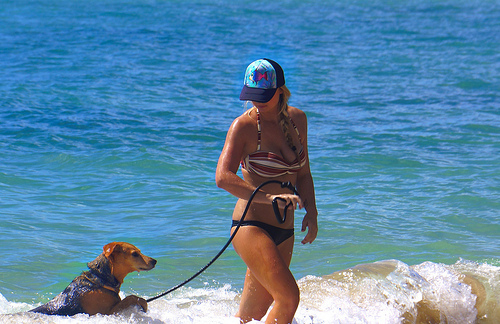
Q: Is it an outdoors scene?
A: Yes, it is outdoors.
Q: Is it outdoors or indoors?
A: It is outdoors.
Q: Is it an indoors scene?
A: No, it is outdoors.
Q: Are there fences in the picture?
A: No, there are no fences.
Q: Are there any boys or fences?
A: No, there are no fences or boys.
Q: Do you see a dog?
A: Yes, there is a dog.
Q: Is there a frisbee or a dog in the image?
A: Yes, there is a dog.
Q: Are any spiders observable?
A: No, there are no spiders.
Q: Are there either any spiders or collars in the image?
A: No, there are no spiders or collars.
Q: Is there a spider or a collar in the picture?
A: No, there are no spiders or collars.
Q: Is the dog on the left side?
A: Yes, the dog is on the left of the image.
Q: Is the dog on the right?
A: No, the dog is on the left of the image.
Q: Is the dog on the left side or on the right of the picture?
A: The dog is on the left of the image.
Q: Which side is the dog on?
A: The dog is on the left of the image.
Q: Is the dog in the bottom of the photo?
A: Yes, the dog is in the bottom of the image.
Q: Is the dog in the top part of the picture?
A: No, the dog is in the bottom of the image.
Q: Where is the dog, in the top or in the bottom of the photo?
A: The dog is in the bottom of the image.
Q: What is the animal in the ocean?
A: The animal is a dog.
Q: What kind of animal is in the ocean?
A: The animal is a dog.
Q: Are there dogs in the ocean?
A: Yes, there is a dog in the ocean.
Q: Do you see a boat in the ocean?
A: No, there is a dog in the ocean.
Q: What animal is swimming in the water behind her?
A: The dog is swimming in the water.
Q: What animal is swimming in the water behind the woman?
A: The animal is a dog.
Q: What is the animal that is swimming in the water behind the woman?
A: The animal is a dog.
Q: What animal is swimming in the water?
A: The animal is a dog.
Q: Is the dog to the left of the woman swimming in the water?
A: Yes, the dog is swimming in the water.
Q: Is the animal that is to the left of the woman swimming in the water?
A: Yes, the dog is swimming in the water.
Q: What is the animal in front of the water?
A: The animal is a dog.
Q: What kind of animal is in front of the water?
A: The animal is a dog.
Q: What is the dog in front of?
A: The dog is in front of the water.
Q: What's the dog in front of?
A: The dog is in front of the water.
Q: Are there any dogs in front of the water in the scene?
A: Yes, there is a dog in front of the water.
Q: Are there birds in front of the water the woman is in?
A: No, there is a dog in front of the water.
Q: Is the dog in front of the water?
A: Yes, the dog is in front of the water.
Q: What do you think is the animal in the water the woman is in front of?
A: The animal is a dog.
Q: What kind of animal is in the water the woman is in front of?
A: The animal is a dog.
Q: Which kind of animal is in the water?
A: The animal is a dog.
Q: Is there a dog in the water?
A: Yes, there is a dog in the water.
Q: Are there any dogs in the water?
A: Yes, there is a dog in the water.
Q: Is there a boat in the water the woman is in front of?
A: No, there is a dog in the water.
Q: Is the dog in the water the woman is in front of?
A: Yes, the dog is in the water.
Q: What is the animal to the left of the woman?
A: The animal is a dog.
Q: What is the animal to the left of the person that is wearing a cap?
A: The animal is a dog.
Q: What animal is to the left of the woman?
A: The animal is a dog.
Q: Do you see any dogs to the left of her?
A: Yes, there is a dog to the left of the woman.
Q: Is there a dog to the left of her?
A: Yes, there is a dog to the left of the woman.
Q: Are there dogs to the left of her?
A: Yes, there is a dog to the left of the woman.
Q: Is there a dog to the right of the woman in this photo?
A: No, the dog is to the left of the woman.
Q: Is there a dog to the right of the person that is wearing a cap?
A: No, the dog is to the left of the woman.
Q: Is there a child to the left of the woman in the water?
A: No, there is a dog to the left of the woman.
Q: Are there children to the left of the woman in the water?
A: No, there is a dog to the left of the woman.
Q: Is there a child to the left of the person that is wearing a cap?
A: No, there is a dog to the left of the woman.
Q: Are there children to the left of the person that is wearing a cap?
A: No, there is a dog to the left of the woman.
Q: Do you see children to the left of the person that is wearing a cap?
A: No, there is a dog to the left of the woman.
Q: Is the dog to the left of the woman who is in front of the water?
A: Yes, the dog is to the left of the woman.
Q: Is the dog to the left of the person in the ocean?
A: Yes, the dog is to the left of the woman.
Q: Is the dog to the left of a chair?
A: No, the dog is to the left of the woman.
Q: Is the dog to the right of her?
A: No, the dog is to the left of a woman.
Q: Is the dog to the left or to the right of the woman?
A: The dog is to the left of the woman.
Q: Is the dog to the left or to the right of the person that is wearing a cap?
A: The dog is to the left of the woman.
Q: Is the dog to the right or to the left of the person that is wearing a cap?
A: The dog is to the left of the woman.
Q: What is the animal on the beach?
A: The animal is a dog.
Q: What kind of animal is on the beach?
A: The animal is a dog.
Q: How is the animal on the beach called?
A: The animal is a dog.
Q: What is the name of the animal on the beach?
A: The animal is a dog.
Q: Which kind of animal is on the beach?
A: The animal is a dog.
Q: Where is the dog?
A: The dog is on the beach.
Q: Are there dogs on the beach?
A: Yes, there is a dog on the beach.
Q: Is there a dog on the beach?
A: Yes, there is a dog on the beach.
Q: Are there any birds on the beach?
A: No, there is a dog on the beach.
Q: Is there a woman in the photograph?
A: Yes, there is a woman.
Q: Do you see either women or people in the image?
A: Yes, there is a woman.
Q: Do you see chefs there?
A: No, there are no chefs.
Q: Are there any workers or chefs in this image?
A: No, there are no chefs or workers.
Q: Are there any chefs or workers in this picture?
A: No, there are no chefs or workers.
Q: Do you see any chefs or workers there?
A: No, there are no chefs or workers.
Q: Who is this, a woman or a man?
A: This is a woman.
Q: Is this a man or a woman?
A: This is a woman.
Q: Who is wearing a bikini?
A: The woman is wearing a bikini.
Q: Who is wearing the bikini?
A: The woman is wearing a bikini.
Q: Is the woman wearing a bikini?
A: Yes, the woman is wearing a bikini.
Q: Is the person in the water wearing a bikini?
A: Yes, the woman is wearing a bikini.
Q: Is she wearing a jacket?
A: No, the woman is wearing a bikini.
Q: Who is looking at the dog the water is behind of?
A: The woman is looking at the dog.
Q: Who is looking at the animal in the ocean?
A: The woman is looking at the dog.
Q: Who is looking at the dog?
A: The woman is looking at the dog.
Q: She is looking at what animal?
A: The woman is looking at the dog.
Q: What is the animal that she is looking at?
A: The animal is a dog.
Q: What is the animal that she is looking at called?
A: The animal is a dog.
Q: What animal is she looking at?
A: The woman is looking at the dog.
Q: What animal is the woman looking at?
A: The woman is looking at the dog.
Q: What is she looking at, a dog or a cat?
A: The woman is looking at a dog.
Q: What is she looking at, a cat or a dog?
A: The woman is looking at a dog.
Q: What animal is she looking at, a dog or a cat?
A: The woman is looking at a dog.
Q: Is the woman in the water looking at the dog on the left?
A: Yes, the woman is looking at the dog.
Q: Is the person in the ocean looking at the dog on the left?
A: Yes, the woman is looking at the dog.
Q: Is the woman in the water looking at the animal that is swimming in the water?
A: Yes, the woman is looking at the dog.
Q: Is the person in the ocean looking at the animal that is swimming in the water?
A: Yes, the woman is looking at the dog.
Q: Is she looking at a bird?
A: No, the woman is looking at the dog.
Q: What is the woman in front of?
A: The woman is in front of the water.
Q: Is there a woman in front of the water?
A: Yes, there is a woman in front of the water.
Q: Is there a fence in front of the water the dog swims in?
A: No, there is a woman in front of the water.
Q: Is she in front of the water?
A: Yes, the woman is in front of the water.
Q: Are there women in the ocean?
A: Yes, there is a woman in the ocean.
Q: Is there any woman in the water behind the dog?
A: Yes, there is a woman in the water.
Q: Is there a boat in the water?
A: No, there is a woman in the water.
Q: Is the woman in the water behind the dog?
A: Yes, the woman is in the water.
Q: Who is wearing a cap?
A: The woman is wearing a cap.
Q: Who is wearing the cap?
A: The woman is wearing a cap.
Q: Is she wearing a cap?
A: Yes, the woman is wearing a cap.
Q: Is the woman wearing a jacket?
A: No, the woman is wearing a cap.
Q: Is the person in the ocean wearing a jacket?
A: No, the woman is wearing a cap.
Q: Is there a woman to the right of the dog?
A: Yes, there is a woman to the right of the dog.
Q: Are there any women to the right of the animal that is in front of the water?
A: Yes, there is a woman to the right of the dog.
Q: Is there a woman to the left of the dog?
A: No, the woman is to the right of the dog.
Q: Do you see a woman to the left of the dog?
A: No, the woman is to the right of the dog.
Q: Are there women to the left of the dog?
A: No, the woman is to the right of the dog.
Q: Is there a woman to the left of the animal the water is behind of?
A: No, the woman is to the right of the dog.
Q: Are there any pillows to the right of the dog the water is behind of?
A: No, there is a woman to the right of the dog.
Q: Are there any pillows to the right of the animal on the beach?
A: No, there is a woman to the right of the dog.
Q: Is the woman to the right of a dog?
A: Yes, the woman is to the right of a dog.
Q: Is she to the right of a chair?
A: No, the woman is to the right of a dog.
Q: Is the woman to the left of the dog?
A: No, the woman is to the right of the dog.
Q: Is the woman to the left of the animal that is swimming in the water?
A: No, the woman is to the right of the dog.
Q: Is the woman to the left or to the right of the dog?
A: The woman is to the right of the dog.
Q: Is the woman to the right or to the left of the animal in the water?
A: The woman is to the right of the dog.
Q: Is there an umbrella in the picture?
A: No, there are no umbrellas.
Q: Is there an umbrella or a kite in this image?
A: No, there are no umbrellas or kites.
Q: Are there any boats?
A: No, there are no boats.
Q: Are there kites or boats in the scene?
A: No, there are no boats or kites.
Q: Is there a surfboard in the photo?
A: No, there are no surfboards.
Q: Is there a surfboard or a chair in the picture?
A: No, there are no surfboards or chairs.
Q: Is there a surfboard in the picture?
A: No, there are no surfboards.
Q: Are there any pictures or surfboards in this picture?
A: No, there are no surfboards or pictures.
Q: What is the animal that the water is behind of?
A: The animal is a dog.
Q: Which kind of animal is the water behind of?
A: The water is behind the dog.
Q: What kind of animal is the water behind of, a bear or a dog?
A: The water is behind a dog.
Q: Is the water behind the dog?
A: Yes, the water is behind the dog.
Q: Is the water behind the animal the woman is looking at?
A: Yes, the water is behind the dog.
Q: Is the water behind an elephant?
A: No, the water is behind the dog.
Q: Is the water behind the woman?
A: Yes, the water is behind the woman.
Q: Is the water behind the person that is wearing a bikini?
A: Yes, the water is behind the woman.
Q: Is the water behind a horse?
A: No, the water is behind the woman.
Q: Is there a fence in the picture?
A: No, there are no fences.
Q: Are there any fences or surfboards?
A: No, there are no fences or surfboards.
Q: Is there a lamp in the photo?
A: No, there are no lamps.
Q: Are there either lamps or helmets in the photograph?
A: No, there are no lamps or helmets.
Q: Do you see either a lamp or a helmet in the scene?
A: No, there are no lamps or helmets.